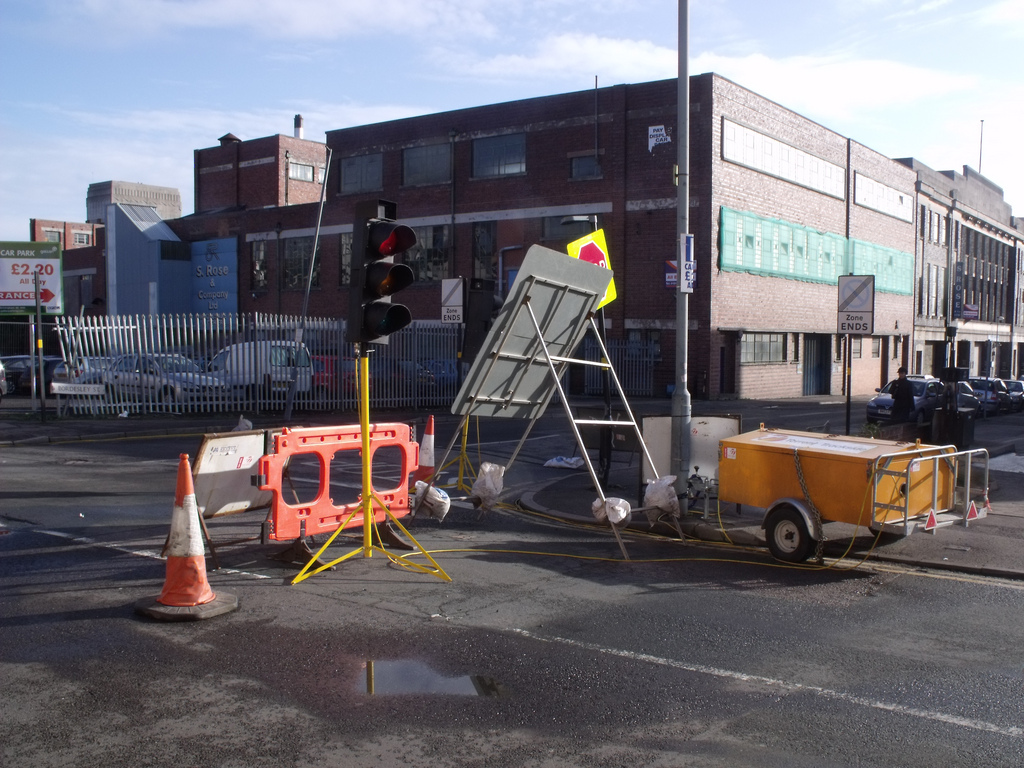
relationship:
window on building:
[546, 206, 570, 229] [0, 69, 1021, 396]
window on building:
[741, 329, 786, 358] [0, 69, 1021, 396]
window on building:
[869, 336, 883, 357] [0, 69, 1021, 396]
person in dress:
[885, 365, 916, 435] [886, 373, 923, 436]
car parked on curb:
[1009, 380, 1022, 412] [849, 384, 866, 405]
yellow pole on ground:
[283, 357, 452, 605] [203, 557, 570, 698]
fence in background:
[43, 313, 329, 421] [2, 13, 465, 429]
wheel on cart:
[751, 497, 821, 565] [713, 417, 992, 567]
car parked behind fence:
[102, 354, 232, 409] [49, 311, 302, 420]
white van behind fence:
[204, 338, 316, 400] [48, 314, 352, 412]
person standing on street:
[886, 365, 918, 438] [801, 414, 922, 433]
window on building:
[240, 148, 276, 167] [0, 69, 1021, 396]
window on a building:
[288, 161, 315, 183] [0, 69, 1021, 396]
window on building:
[202, 155, 229, 174] [0, 69, 1021, 396]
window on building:
[335, 149, 383, 191] [0, 69, 1021, 396]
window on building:
[401, 148, 453, 183] [0, 69, 1021, 396]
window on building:
[469, 130, 524, 168] [0, 69, 1021, 396]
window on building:
[466, 221, 493, 288] [0, 69, 1021, 396]